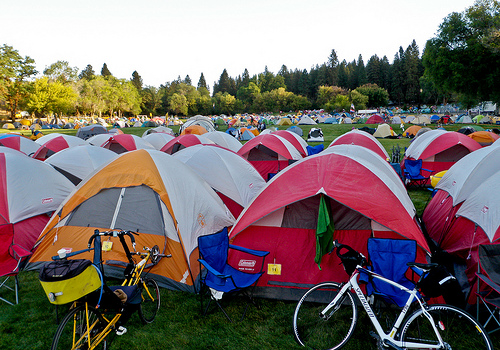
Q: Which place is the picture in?
A: It is at the park.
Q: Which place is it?
A: It is a park.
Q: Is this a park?
A: Yes, it is a park.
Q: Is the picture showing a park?
A: Yes, it is showing a park.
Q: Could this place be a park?
A: Yes, it is a park.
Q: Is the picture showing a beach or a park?
A: It is showing a park.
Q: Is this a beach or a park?
A: It is a park.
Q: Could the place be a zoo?
A: No, it is a park.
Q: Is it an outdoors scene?
A: Yes, it is outdoors.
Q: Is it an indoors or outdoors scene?
A: It is outdoors.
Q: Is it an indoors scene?
A: No, it is outdoors.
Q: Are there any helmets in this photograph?
A: No, there are no helmets.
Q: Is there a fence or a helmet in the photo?
A: No, there are no helmets or fences.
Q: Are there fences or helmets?
A: No, there are no helmets or fences.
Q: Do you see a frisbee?
A: No, there are no frisbees.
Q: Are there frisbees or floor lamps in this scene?
A: No, there are no frisbees or floor lamps.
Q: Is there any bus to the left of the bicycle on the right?
A: No, there is a tent to the left of the bicycle.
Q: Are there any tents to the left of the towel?
A: Yes, there is a tent to the left of the towel.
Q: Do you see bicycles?
A: Yes, there is a bicycle.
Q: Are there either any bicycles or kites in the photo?
A: Yes, there is a bicycle.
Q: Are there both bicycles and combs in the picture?
A: No, there is a bicycle but no combs.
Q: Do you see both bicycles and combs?
A: No, there is a bicycle but no combs.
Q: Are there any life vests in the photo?
A: No, there are no life vests.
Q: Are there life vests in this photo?
A: No, there are no life vests.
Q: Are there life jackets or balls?
A: No, there are no life jackets or balls.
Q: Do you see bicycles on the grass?
A: Yes, there is a bicycle on the grass.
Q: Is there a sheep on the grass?
A: No, there is a bicycle on the grass.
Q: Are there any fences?
A: No, there are no fences.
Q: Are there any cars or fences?
A: No, there are no fences or cars.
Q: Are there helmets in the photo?
A: No, there are no helmets.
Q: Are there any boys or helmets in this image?
A: No, there are no helmets or boys.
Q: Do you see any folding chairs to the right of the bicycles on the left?
A: Yes, there is a folding chair to the right of the bicycles.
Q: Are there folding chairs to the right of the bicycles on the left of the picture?
A: Yes, there is a folding chair to the right of the bicycles.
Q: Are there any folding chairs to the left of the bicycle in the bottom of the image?
A: Yes, there is a folding chair to the left of the bicycle.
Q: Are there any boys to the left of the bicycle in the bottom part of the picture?
A: No, there is a folding chair to the left of the bicycle.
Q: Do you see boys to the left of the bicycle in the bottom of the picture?
A: No, there is a folding chair to the left of the bicycle.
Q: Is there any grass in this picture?
A: Yes, there is grass.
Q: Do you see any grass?
A: Yes, there is grass.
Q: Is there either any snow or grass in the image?
A: Yes, there is grass.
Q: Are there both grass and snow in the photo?
A: No, there is grass but no snow.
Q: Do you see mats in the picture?
A: No, there are no mats.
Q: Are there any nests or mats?
A: No, there are no mats or nests.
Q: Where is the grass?
A: The grass is on the field.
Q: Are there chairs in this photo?
A: Yes, there is a chair.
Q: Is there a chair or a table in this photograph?
A: Yes, there is a chair.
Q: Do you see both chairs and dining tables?
A: No, there is a chair but no dining tables.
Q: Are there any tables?
A: No, there are no tables.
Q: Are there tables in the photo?
A: No, there are no tables.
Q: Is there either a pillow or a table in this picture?
A: No, there are no tables or pillows.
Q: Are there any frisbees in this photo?
A: No, there are no frisbees.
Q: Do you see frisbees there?
A: No, there are no frisbees.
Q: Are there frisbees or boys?
A: No, there are no frisbees or boys.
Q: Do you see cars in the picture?
A: No, there are no cars.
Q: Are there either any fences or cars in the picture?
A: No, there are no cars or fences.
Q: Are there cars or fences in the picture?
A: No, there are no cars or fences.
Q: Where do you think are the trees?
A: The trees are in the park.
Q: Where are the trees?
A: The trees are in the park.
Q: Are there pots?
A: No, there are no pots.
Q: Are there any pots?
A: No, there are no pots.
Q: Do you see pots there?
A: No, there are no pots.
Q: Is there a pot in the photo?
A: No, there are no pots.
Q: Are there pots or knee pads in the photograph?
A: No, there are no pots or knee pads.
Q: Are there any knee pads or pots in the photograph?
A: No, there are no pots or knee pads.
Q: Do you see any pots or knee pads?
A: No, there are no pots or knee pads.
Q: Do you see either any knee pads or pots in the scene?
A: No, there are no pots or knee pads.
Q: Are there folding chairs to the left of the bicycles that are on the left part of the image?
A: Yes, there is a folding chair to the left of the bicycles.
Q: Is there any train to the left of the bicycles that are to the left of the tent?
A: No, there is a folding chair to the left of the bicycles.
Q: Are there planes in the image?
A: No, there are no planes.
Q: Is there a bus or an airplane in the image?
A: No, there are no airplanes or buses.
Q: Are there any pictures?
A: No, there are no pictures.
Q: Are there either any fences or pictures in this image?
A: No, there are no pictures or fences.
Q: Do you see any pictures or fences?
A: No, there are no pictures or fences.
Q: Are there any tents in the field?
A: Yes, there are tents in the field.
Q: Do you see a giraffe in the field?
A: No, there are tents in the field.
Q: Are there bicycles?
A: Yes, there are bicycles.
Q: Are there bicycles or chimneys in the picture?
A: Yes, there are bicycles.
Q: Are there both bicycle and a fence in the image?
A: No, there are bicycles but no fences.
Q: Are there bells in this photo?
A: No, there are no bells.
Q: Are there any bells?
A: No, there are no bells.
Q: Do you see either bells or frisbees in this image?
A: No, there are no bells or frisbees.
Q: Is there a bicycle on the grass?
A: Yes, there are bicycles on the grass.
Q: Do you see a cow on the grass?
A: No, there are bicycles on the grass.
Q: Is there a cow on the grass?
A: No, there are bicycles on the grass.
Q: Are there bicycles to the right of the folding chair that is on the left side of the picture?
A: Yes, there are bicycles to the right of the folding chair.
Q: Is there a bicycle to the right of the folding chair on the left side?
A: Yes, there are bicycles to the right of the folding chair.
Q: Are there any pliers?
A: No, there are no pliers.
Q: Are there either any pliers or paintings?
A: No, there are no pliers or paintings.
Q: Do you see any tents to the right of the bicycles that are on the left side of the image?
A: Yes, there is a tent to the right of the bicycles.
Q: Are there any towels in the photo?
A: Yes, there is a towel.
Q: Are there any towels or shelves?
A: Yes, there is a towel.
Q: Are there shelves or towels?
A: Yes, there is a towel.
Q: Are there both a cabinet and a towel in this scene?
A: No, there is a towel but no cabinets.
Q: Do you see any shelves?
A: No, there are no shelves.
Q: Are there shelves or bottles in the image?
A: No, there are no shelves or bottles.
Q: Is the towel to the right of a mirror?
A: No, the towel is to the right of the tent.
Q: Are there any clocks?
A: No, there are no clocks.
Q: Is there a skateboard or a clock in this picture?
A: No, there are no clocks or skateboards.